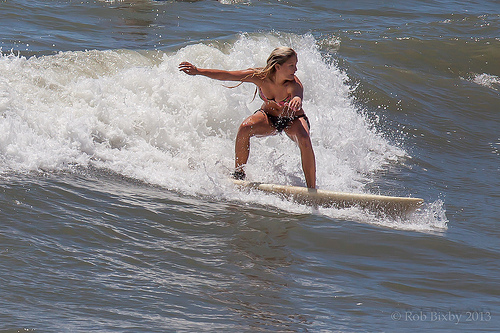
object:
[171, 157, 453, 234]
surfboard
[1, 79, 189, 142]
water spray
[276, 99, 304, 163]
water dripping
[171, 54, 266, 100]
woman's arm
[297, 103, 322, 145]
sunlight glistening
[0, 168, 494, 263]
water calming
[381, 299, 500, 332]
watermark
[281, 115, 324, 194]
leg on surfboard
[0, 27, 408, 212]
foamy wave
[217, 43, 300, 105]
blond hair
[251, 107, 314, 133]
black bikini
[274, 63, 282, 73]
ear on female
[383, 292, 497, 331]
copyright sign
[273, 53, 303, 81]
girls face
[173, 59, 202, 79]
girls hand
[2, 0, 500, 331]
calm water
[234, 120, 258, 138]
knees for the girl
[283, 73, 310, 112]
woman's arms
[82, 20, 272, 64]
sun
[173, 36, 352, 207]
girl